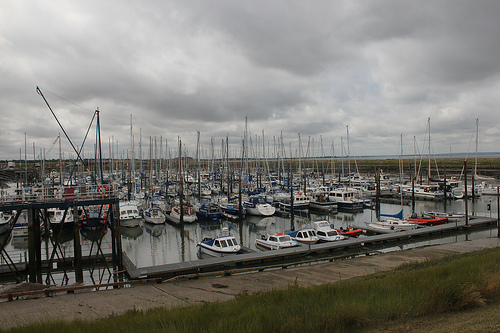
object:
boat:
[196, 236, 241, 258]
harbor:
[1, 161, 494, 300]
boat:
[255, 232, 302, 249]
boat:
[289, 229, 320, 244]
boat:
[314, 220, 345, 241]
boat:
[336, 227, 363, 238]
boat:
[365, 216, 417, 230]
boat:
[406, 213, 448, 226]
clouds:
[3, 1, 499, 156]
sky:
[1, 1, 500, 164]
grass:
[2, 245, 499, 333]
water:
[2, 179, 500, 301]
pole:
[288, 142, 296, 231]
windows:
[220, 240, 227, 247]